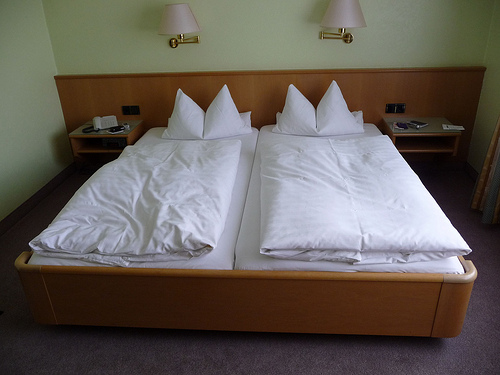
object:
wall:
[1, 1, 58, 178]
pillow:
[162, 83, 253, 141]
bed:
[15, 123, 477, 338]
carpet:
[1, 336, 497, 374]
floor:
[5, 156, 499, 372]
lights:
[317, 1, 366, 47]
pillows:
[271, 79, 366, 138]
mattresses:
[204, 250, 234, 272]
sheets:
[261, 134, 456, 265]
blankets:
[256, 134, 473, 267]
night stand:
[67, 118, 147, 171]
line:
[231, 135, 261, 270]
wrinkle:
[84, 189, 203, 236]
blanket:
[29, 137, 243, 260]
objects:
[80, 127, 96, 133]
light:
[157, 3, 203, 49]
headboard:
[52, 65, 486, 160]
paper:
[440, 122, 466, 131]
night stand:
[383, 115, 464, 157]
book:
[406, 119, 428, 129]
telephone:
[90, 112, 119, 130]